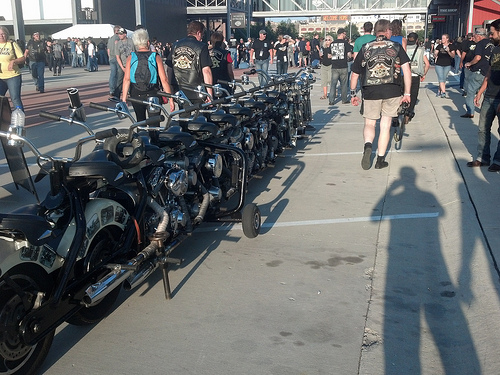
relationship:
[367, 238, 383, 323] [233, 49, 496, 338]
line on ground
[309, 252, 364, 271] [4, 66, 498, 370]
mark on ground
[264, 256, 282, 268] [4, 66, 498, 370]
mark on ground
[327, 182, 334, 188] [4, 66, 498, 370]
mark on ground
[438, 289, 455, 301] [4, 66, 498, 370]
mark on ground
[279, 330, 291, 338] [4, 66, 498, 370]
mark on ground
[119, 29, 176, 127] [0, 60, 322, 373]
woman next to bikes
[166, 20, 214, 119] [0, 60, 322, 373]
man next to bikes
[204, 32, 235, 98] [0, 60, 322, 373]
man next to bikes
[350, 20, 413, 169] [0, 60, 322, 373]
man next to bikes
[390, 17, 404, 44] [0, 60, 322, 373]
person next to bikes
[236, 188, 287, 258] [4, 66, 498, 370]
wheel on ground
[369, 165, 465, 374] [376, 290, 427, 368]
shadow of leg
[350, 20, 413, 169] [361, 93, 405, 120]
man wearing shorts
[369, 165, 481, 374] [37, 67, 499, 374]
shadow stretches across sidewalk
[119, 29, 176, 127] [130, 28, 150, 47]
woman has silver hair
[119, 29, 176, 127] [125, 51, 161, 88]
woman wears vest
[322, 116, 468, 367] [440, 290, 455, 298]
sidewalk has stain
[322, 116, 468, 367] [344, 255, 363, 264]
sidewalk has stain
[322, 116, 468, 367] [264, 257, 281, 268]
sidewalk has stain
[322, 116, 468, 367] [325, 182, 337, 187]
sidewalk has stain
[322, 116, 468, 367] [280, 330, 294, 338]
sidewalk has stain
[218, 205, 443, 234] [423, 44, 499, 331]
line on sidewalk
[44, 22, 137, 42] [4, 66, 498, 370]
tent opposite of ground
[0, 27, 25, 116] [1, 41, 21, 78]
woman wearing t-shirt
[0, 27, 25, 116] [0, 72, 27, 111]
woman wearing jeans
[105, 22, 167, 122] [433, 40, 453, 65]
woman wearing t-shirt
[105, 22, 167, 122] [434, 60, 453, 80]
woman wearing capris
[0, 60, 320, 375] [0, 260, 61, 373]
bikes has a wheel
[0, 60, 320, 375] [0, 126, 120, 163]
bikes has handles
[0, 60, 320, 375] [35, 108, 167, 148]
bikes has handles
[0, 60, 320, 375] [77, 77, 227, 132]
bikes has handles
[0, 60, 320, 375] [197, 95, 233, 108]
bikes has handles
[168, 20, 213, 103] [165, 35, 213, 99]
man has jacket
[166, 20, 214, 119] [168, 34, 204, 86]
man has jacket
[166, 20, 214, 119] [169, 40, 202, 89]
man has jacket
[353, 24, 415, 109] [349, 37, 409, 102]
man has shirt